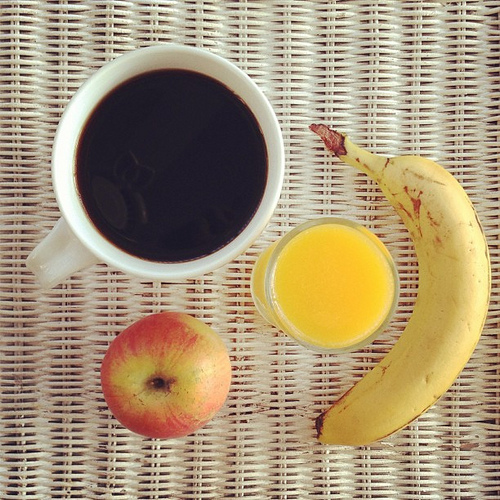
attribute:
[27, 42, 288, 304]
coffee cup — full, white, aerial view, ceramic, fresh, steaming, coffee mug, glass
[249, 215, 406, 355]
glass — full, clear, orange juice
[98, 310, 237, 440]
apple — round, unpeeled, two colors, red, yellow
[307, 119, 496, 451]
banana — yellow, ripe, unpeeled, curved, whole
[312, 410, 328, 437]
spot — dark